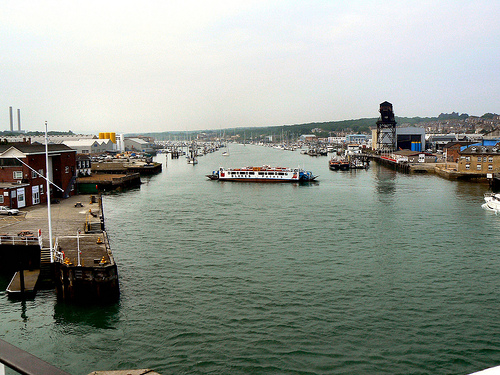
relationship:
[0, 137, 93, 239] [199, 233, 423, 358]
house near water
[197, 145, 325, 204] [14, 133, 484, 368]
boat crossing water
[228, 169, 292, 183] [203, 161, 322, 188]
windows on boat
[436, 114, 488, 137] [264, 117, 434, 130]
tress on hillside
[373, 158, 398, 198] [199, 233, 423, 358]
shadow in water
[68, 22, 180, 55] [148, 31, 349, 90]
clouds in sky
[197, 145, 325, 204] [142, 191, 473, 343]
boat in middle of water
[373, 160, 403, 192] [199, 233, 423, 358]
shadow in water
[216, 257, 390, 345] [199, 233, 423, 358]
ripples on water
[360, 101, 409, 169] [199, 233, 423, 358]
tower by water